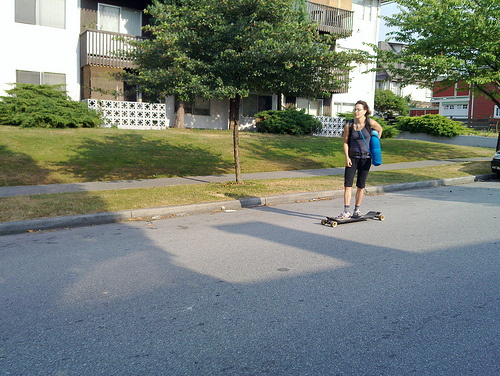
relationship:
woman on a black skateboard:
[339, 98, 383, 223] [318, 209, 389, 229]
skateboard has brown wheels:
[318, 209, 389, 229] [321, 215, 385, 227]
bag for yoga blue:
[370, 129, 383, 168] [373, 141, 380, 151]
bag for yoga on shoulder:
[370, 129, 383, 168] [365, 117, 382, 131]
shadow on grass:
[72, 131, 235, 181] [2, 125, 476, 179]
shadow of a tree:
[72, 131, 235, 181] [123, 1, 347, 187]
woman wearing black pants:
[339, 98, 383, 223] [343, 157, 374, 191]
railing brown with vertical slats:
[77, 29, 154, 74] [94, 33, 107, 67]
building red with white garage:
[406, 74, 498, 130] [436, 97, 474, 121]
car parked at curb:
[490, 148, 500, 178] [425, 173, 499, 189]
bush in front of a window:
[1, 83, 106, 136] [11, 68, 71, 100]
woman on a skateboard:
[339, 98, 383, 223] [318, 209, 389, 229]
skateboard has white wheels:
[318, 209, 389, 229] [321, 215, 385, 227]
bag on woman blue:
[370, 129, 383, 168] [373, 141, 380, 151]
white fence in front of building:
[80, 98, 173, 130] [2, 1, 385, 145]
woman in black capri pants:
[339, 98, 383, 223] [343, 157, 374, 191]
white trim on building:
[469, 76, 477, 119] [406, 74, 498, 130]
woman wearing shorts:
[339, 98, 383, 223] [343, 157, 374, 191]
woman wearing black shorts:
[339, 98, 383, 223] [343, 157, 374, 191]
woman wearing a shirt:
[339, 98, 383, 223] [346, 120, 371, 162]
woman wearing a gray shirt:
[339, 98, 383, 223] [346, 120, 371, 162]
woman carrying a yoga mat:
[339, 98, 383, 223] [370, 129, 383, 168]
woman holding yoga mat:
[339, 98, 383, 223] [370, 129, 383, 168]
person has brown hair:
[339, 98, 383, 223] [355, 98, 374, 115]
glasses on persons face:
[351, 107, 367, 111] [351, 104, 367, 119]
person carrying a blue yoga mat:
[339, 98, 383, 223] [367, 129, 388, 170]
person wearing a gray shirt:
[339, 98, 383, 223] [346, 120, 371, 162]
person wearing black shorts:
[339, 98, 383, 223] [343, 157, 374, 191]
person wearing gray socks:
[339, 98, 383, 223] [342, 203, 363, 213]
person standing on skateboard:
[339, 98, 383, 223] [318, 209, 389, 229]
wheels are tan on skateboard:
[321, 215, 385, 227] [318, 209, 389, 229]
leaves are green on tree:
[167, 11, 208, 33] [123, 1, 347, 187]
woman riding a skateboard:
[339, 98, 383, 223] [318, 209, 389, 229]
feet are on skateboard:
[335, 212, 367, 220] [318, 209, 389, 229]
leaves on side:
[26, 228, 79, 240] [16, 199, 269, 275]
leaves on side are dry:
[26, 228, 79, 240] [28, 228, 36, 234]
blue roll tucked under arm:
[370, 129, 383, 168] [373, 121, 385, 139]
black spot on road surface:
[272, 264, 295, 275] [2, 187, 496, 375]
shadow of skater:
[216, 187, 332, 223] [339, 98, 383, 223]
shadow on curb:
[216, 187, 332, 223] [209, 193, 334, 213]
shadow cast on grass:
[72, 131, 235, 181] [2, 125, 476, 179]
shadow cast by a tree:
[72, 131, 235, 181] [123, 1, 347, 187]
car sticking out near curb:
[490, 148, 500, 178] [425, 173, 499, 189]